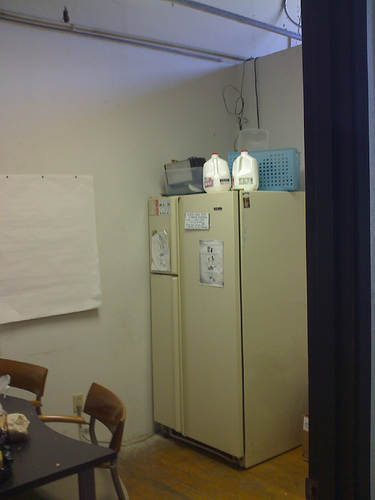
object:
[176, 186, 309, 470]
refrigerator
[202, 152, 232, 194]
milk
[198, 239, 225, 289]
paper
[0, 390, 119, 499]
table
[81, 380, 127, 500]
chair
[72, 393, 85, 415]
outlet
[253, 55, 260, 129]
cords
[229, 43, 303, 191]
wall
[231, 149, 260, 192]
container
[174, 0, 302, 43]
pipes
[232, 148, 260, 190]
milk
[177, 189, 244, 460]
door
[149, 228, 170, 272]
paper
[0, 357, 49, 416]
chair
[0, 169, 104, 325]
paper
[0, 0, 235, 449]
wall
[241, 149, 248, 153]
cap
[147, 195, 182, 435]
freezer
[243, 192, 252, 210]
magnet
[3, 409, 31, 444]
food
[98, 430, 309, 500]
floor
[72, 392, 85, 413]
socket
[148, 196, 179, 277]
door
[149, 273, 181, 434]
door